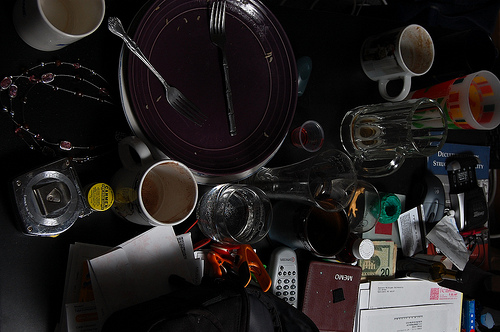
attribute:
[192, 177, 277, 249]
glass — drinking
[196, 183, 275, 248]
water glass — clear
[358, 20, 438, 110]
cup — white, black, dirty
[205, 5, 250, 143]
fork — silver, metal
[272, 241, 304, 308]
control — remote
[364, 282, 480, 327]
mail — stack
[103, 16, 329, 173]
plate — red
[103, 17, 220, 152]
fork — used, steel, spoon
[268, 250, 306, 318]
control — grey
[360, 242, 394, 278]
$20 bill — twenty dollar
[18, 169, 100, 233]
tape — silver, metal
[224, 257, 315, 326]
bag — black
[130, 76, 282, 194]
plate — red, white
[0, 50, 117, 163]
necklace — beautiful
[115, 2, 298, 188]
dish — purple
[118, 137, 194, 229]
cup — coffee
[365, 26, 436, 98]
cup — coffee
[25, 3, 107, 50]
cup — coffee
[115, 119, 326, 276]
dishes — dirty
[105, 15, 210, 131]
utensil — eating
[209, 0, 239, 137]
utensil — eating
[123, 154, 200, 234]
cup — coffee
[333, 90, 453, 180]
glass — big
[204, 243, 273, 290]
clips — orange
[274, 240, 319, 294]
control — white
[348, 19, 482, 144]
dishes — dirty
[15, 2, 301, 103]
dishes — dirty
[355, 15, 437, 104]
cup — coffee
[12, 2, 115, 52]
cup — coffee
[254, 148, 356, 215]
glass — drinking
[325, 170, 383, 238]
glass — drinking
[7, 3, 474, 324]
table — filled